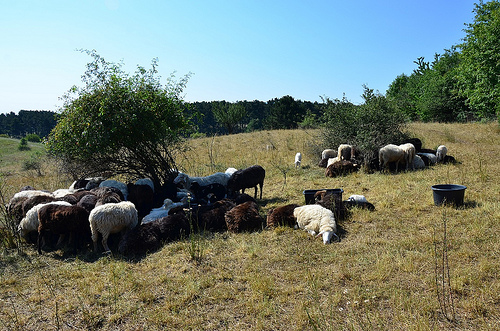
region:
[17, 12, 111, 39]
white clouds against blue sky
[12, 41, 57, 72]
white clouds against blue sky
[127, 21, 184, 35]
white clouds against blue sky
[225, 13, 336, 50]
white clouds against blue sky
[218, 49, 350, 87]
white clouds against blue sky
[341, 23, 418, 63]
white clouds against blue sky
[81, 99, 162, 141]
large green bush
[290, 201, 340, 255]
white sheep lying on ground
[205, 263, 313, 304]
short green and brown grass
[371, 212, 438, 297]
short grass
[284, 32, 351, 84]
the sky is clear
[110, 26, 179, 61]
the sky is clear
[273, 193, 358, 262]
the sheep is sleeping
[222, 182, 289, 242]
the sheep is sleeping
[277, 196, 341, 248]
the sheep is white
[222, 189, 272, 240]
the sheep is brown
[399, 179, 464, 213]
the bucket is black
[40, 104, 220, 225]
sheep under the tree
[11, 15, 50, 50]
white clouds in blue sky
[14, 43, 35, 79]
white clouds in blue sky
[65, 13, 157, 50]
white clouds in blue sky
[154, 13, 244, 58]
white clouds in blue sky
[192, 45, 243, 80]
white clouds in blue sky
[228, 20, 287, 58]
white clouds in blue sky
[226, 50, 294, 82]
white clouds in blue sky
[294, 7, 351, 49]
white clouds in blue sky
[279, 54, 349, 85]
white clouds in blue sky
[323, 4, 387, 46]
white clouds in blue sky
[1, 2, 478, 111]
blue of daytime sky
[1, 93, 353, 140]
line of trees on horizon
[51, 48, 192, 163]
green leaves on bush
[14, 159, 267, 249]
herd of sheep in a cluster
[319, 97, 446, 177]
sheep gathered around bush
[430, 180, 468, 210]
black bucket with round opening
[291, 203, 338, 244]
top of reclined sheep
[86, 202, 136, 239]
long wool on white sheep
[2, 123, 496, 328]
dried grass on ground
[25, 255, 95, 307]
short green and brown grass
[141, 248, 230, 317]
short green and brown grass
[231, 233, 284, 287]
short green and brown grass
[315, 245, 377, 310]
short green and brown grass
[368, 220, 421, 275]
short green and brown grass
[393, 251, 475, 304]
short green and brown grass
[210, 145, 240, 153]
short green and brown grass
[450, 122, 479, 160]
short green and brown grass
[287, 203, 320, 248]
sheep